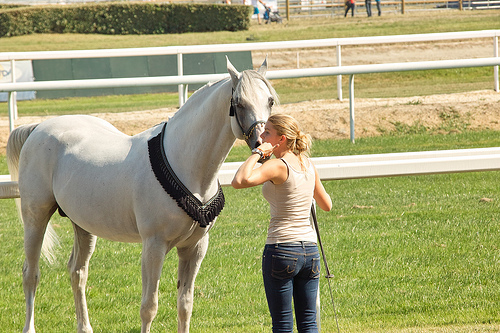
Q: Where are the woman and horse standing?
A: In the grass.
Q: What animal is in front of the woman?
A: Horse.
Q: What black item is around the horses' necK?
A: Collar.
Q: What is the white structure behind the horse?
A: Railing.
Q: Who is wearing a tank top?
A: The woman.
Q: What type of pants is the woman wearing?
A: Jeans.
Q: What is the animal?
A: A horse.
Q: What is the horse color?
A: White.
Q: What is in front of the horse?
A: A female.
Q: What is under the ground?
A: Grass.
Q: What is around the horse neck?
A: A hornes.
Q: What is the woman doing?
A: Touching her ears.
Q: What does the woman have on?
A: Jeans.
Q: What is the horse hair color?
A: White.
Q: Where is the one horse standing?
A: In the grass.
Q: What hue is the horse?
A: White.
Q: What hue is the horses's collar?
A: Black.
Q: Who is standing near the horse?
A: A woman.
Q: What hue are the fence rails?
A: White.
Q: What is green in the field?
A: Green grass.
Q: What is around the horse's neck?
A: Brown girdle.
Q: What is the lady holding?
A: The horse's bridle.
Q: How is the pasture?
A: Green.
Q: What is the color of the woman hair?
A: Is blonde.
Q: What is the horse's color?
A: Is white.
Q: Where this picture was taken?
A: In a camp.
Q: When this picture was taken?
A: During the day.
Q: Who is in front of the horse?
A: The woman.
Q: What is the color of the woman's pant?
A: Is blue.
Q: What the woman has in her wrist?
A: A watch.